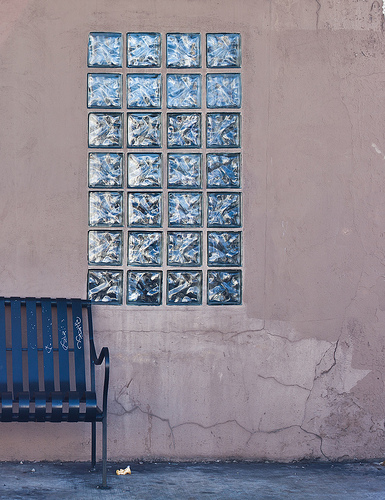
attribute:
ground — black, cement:
[6, 458, 384, 499]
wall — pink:
[17, 7, 383, 350]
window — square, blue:
[84, 31, 241, 303]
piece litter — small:
[102, 458, 140, 496]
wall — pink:
[246, 93, 348, 190]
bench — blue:
[9, 264, 127, 452]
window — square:
[82, 22, 247, 317]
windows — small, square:
[83, 27, 124, 68]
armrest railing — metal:
[86, 302, 118, 407]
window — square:
[127, 33, 160, 69]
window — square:
[87, 30, 122, 65]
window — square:
[167, 31, 200, 66]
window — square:
[205, 30, 239, 67]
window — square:
[88, 72, 122, 109]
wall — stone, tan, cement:
[0, 0, 383, 462]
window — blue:
[163, 24, 244, 156]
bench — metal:
[1, 286, 106, 485]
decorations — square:
[75, 22, 263, 311]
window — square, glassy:
[207, 269, 243, 305]